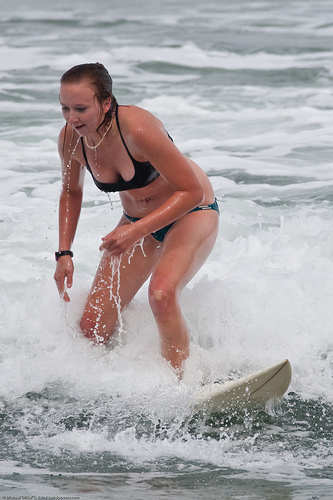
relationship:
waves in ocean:
[138, 19, 322, 121] [5, 7, 324, 62]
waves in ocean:
[138, 19, 322, 121] [22, 26, 332, 101]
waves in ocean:
[215, 157, 332, 180] [3, 3, 331, 82]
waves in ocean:
[138, 19, 322, 121] [3, 3, 331, 82]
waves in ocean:
[260, 181, 332, 201] [3, 3, 331, 82]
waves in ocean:
[4, 45, 130, 65] [3, 3, 331, 82]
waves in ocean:
[0, 98, 57, 107] [3, 3, 331, 82]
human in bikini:
[53, 61, 220, 383] [81, 135, 182, 204]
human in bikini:
[53, 61, 220, 383] [114, 197, 228, 224]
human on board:
[53, 61, 220, 383] [144, 351, 303, 426]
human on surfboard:
[53, 61, 220, 383] [175, 348, 294, 427]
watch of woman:
[54, 249, 73, 260] [34, 53, 222, 345]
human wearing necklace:
[53, 61, 220, 383] [73, 123, 128, 153]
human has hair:
[53, 61, 220, 383] [60, 60, 128, 110]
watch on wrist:
[53, 249, 73, 260] [55, 248, 71, 259]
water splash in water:
[33, 363, 225, 459] [2, 1, 321, 498]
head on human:
[55, 63, 114, 145] [31, 48, 221, 390]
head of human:
[58, 63, 113, 139] [53, 61, 220, 383]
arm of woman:
[53, 152, 83, 254] [38, 59, 220, 387]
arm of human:
[129, 121, 212, 217] [53, 61, 220, 383]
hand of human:
[99, 223, 138, 258] [53, 61, 220, 383]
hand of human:
[53, 247, 75, 301] [53, 61, 220, 383]